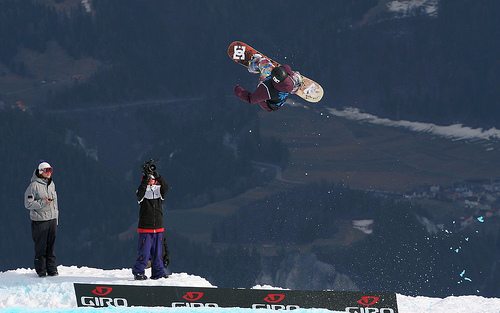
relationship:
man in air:
[220, 51, 305, 118] [2, 2, 500, 293]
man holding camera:
[125, 156, 177, 283] [139, 157, 161, 180]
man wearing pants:
[125, 156, 177, 283] [129, 229, 174, 281]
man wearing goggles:
[21, 157, 62, 278] [38, 160, 58, 175]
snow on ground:
[1, 262, 493, 311] [1, 261, 499, 311]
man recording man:
[125, 156, 177, 283] [220, 51, 305, 118]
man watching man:
[125, 156, 177, 283] [220, 51, 305, 118]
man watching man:
[21, 157, 62, 278] [220, 51, 305, 118]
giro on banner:
[77, 283, 130, 310] [70, 280, 404, 311]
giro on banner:
[168, 286, 222, 311] [70, 280, 404, 311]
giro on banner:
[251, 288, 303, 312] [70, 280, 404, 311]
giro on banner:
[341, 292, 400, 312] [70, 280, 404, 311]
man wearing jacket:
[220, 51, 305, 118] [233, 65, 299, 110]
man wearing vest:
[220, 51, 305, 118] [259, 78, 295, 114]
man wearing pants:
[220, 51, 305, 118] [245, 56, 279, 80]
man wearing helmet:
[220, 51, 305, 118] [269, 64, 291, 87]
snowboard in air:
[222, 37, 327, 104] [2, 2, 500, 293]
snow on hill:
[324, 97, 499, 152] [0, 81, 495, 181]